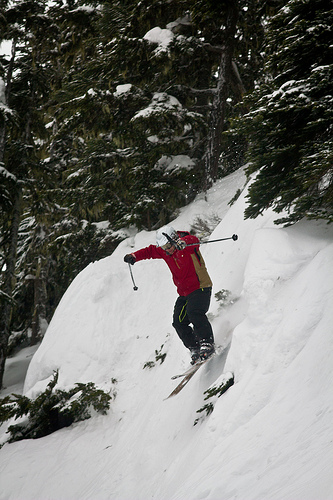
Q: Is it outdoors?
A: Yes, it is outdoors.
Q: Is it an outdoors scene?
A: Yes, it is outdoors.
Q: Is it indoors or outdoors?
A: It is outdoors.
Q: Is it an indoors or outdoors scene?
A: It is outdoors.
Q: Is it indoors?
A: No, it is outdoors.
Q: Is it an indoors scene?
A: No, it is outdoors.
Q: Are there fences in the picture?
A: No, there are no fences.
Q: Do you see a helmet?
A: Yes, there is a helmet.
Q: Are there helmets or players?
A: Yes, there is a helmet.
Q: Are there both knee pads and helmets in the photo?
A: No, there is a helmet but no knee pads.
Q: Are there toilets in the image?
A: No, there are no toilets.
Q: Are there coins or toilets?
A: No, there are no toilets or coins.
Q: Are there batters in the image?
A: No, there are no batters.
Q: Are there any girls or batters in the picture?
A: No, there are no batters or girls.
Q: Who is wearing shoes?
A: The man is wearing shoes.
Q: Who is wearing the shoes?
A: The man is wearing shoes.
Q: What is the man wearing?
A: The man is wearing shoes.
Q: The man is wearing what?
A: The man is wearing shoes.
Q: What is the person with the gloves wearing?
A: The man is wearing shoes.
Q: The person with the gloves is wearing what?
A: The man is wearing shoes.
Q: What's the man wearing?
A: The man is wearing shoes.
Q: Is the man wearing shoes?
A: Yes, the man is wearing shoes.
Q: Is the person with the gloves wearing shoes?
A: Yes, the man is wearing shoes.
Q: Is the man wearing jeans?
A: No, the man is wearing shoes.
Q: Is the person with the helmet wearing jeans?
A: No, the man is wearing shoes.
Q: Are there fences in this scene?
A: No, there are no fences.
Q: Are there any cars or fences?
A: No, there are no fences or cars.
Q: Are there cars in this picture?
A: No, there are no cars.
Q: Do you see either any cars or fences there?
A: No, there are no cars or fences.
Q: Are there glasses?
A: No, there are no glasses.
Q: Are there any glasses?
A: No, there are no glasses.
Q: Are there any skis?
A: Yes, there are skis.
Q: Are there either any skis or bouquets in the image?
A: Yes, there are skis.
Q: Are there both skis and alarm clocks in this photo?
A: No, there are skis but no alarm clocks.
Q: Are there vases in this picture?
A: No, there are no vases.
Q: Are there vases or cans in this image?
A: No, there are no vases or cans.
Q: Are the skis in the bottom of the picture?
A: Yes, the skis are in the bottom of the image.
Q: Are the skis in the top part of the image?
A: No, the skis are in the bottom of the image.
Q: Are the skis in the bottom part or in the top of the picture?
A: The skis are in the bottom of the image.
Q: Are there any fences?
A: No, there are no fences.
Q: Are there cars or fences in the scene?
A: No, there are no fences or cars.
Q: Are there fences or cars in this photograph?
A: No, there are no fences or cars.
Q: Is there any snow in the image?
A: Yes, there is snow.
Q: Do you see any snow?
A: Yes, there is snow.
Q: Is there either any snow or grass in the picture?
A: Yes, there is snow.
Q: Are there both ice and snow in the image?
A: No, there is snow but no ice.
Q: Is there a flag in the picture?
A: No, there are no flags.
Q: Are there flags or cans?
A: No, there are no flags or cans.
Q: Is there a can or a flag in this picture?
A: No, there are no flags or cans.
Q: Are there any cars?
A: No, there are no cars.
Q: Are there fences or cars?
A: No, there are no cars or fences.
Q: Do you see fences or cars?
A: No, there are no cars or fences.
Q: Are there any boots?
A: Yes, there are boots.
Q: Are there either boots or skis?
A: Yes, there are boots.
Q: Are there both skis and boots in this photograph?
A: Yes, there are both boots and skis.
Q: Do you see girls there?
A: No, there are no girls.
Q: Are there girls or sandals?
A: No, there are no girls or sandals.